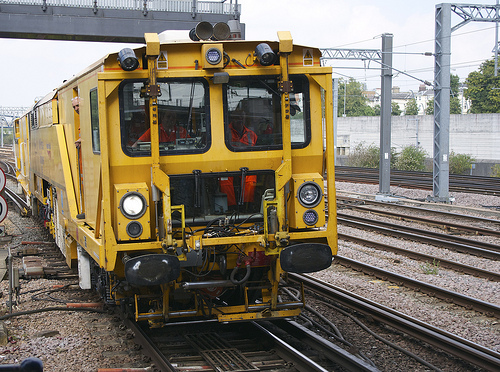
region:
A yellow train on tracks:
[3, 27, 339, 318]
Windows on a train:
[114, 75, 313, 151]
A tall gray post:
[375, 35, 395, 192]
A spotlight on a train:
[252, 44, 272, 64]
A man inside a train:
[216, 109, 256, 203]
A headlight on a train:
[299, 180, 319, 207]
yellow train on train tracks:
[10, 15, 347, 337]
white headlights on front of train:
[121, 177, 326, 242]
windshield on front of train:
[116, 69, 318, 158]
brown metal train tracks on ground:
[286, 188, 498, 370]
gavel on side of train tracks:
[345, 267, 499, 347]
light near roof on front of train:
[203, 46, 221, 64]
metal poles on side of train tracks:
[371, 0, 461, 202]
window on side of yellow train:
[82, 83, 106, 155]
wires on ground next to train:
[0, 233, 106, 328]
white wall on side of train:
[336, 108, 499, 170]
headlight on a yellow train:
[121, 192, 146, 220]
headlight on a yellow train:
[296, 183, 321, 206]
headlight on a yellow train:
[118, 50, 140, 70]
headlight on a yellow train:
[207, 49, 222, 63]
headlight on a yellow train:
[257, 42, 274, 62]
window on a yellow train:
[116, 80, 211, 157]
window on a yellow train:
[222, 72, 311, 148]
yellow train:
[0, 20, 338, 327]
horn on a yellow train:
[187, 22, 233, 41]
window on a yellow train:
[88, 89, 100, 154]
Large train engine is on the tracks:
[14, 26, 406, 351]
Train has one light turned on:
[120, 186, 147, 221]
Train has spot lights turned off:
[108, 30, 285, 80]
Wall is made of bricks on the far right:
[337, 93, 487, 209]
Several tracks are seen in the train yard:
[43, 123, 498, 328]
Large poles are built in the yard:
[255, 15, 480, 255]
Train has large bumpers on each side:
[110, 224, 363, 317]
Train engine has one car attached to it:
[0, 39, 371, 341]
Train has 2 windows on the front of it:
[15, 28, 345, 368]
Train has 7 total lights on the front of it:
[93, 29, 325, 299]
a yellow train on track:
[33, 52, 406, 368]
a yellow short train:
[128, 95, 350, 329]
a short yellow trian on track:
[33, 60, 268, 272]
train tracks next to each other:
[302, 156, 494, 327]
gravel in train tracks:
[353, 138, 425, 270]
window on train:
[128, 86, 158, 141]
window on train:
[234, 54, 347, 138]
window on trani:
[184, 172, 269, 198]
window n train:
[84, 93, 89, 139]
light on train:
[110, 177, 149, 222]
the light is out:
[296, 182, 328, 210]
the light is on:
[117, 197, 144, 218]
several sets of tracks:
[345, 194, 460, 366]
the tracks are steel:
[331, 190, 496, 358]